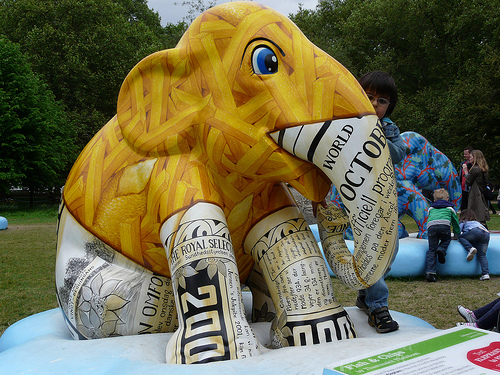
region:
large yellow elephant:
[108, 48, 405, 238]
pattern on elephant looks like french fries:
[149, 110, 272, 205]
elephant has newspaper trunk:
[268, 110, 479, 305]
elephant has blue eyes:
[240, 45, 292, 81]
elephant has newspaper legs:
[141, 203, 270, 370]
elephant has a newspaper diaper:
[44, 200, 170, 348]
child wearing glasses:
[357, 57, 414, 169]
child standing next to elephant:
[316, 48, 423, 360]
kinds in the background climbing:
[399, 156, 488, 303]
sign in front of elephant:
[329, 319, 494, 369]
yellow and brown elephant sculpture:
[61, 15, 396, 185]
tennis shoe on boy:
[368, 311, 402, 333]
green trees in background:
[11, 39, 81, 139]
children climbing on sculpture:
[425, 193, 490, 276]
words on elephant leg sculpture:
[158, 226, 260, 364]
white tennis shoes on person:
[455, 304, 477, 327]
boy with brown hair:
[360, 70, 402, 95]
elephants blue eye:
[246, 43, 283, 77]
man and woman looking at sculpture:
[459, 148, 489, 220]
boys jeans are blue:
[355, 290, 399, 308]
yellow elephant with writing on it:
[45, 4, 437, 359]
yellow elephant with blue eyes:
[45, 2, 435, 354]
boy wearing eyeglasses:
[330, 59, 418, 334]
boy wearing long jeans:
[419, 182, 458, 289]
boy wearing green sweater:
[422, 180, 458, 276]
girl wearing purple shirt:
[456, 199, 498, 284]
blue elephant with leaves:
[331, 106, 470, 253]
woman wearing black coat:
[465, 145, 493, 230]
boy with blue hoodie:
[420, 185, 460, 283]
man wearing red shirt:
[452, 145, 473, 212]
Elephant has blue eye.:
[253, 42, 286, 75]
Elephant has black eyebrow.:
[230, 25, 293, 73]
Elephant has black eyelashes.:
[241, 60, 267, 92]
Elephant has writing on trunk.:
[316, 137, 378, 294]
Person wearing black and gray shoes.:
[364, 287, 402, 336]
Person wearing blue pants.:
[364, 280, 404, 320]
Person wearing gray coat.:
[383, 132, 411, 170]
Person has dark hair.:
[368, 65, 416, 125]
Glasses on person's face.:
[361, 91, 403, 118]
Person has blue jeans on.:
[434, 233, 466, 268]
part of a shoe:
[376, 311, 398, 343]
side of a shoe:
[388, 324, 401, 330]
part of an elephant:
[108, 230, 126, 249]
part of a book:
[374, 350, 396, 356]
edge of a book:
[354, 333, 388, 367]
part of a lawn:
[5, 242, 17, 255]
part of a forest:
[28, 157, 47, 193]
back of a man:
[437, 211, 439, 217]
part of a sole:
[472, 253, 474, 256]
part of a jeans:
[370, 277, 387, 307]